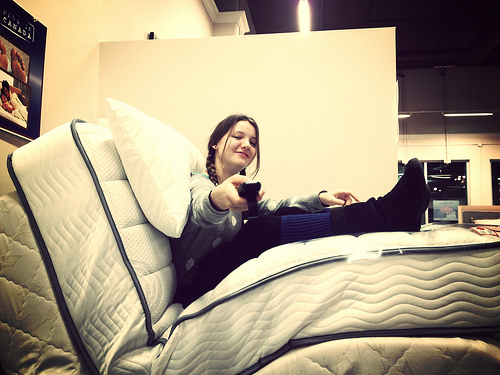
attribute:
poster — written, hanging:
[2, 19, 71, 141]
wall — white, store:
[13, 11, 155, 165]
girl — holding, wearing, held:
[151, 76, 355, 307]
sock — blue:
[334, 168, 427, 245]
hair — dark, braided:
[206, 110, 242, 147]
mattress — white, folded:
[326, 222, 471, 306]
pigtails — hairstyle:
[175, 140, 231, 203]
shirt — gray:
[178, 176, 228, 235]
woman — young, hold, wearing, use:
[163, 118, 309, 263]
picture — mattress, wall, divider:
[48, 39, 443, 359]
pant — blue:
[275, 192, 363, 245]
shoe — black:
[378, 156, 444, 236]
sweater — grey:
[203, 223, 215, 235]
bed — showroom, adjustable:
[101, 194, 461, 372]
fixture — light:
[144, 28, 195, 52]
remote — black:
[252, 171, 256, 191]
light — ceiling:
[242, 6, 322, 65]